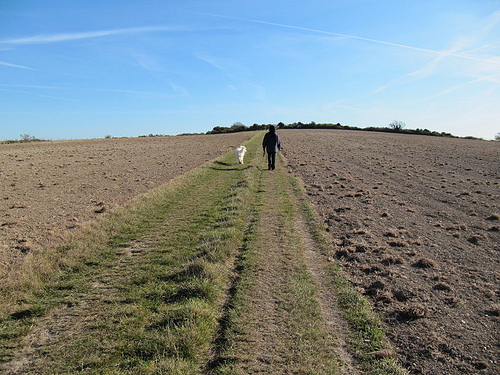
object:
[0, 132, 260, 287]
field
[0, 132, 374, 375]
road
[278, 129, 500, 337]
dirt field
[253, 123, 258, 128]
trees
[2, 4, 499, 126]
sky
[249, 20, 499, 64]
contrail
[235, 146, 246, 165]
animal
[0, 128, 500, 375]
grass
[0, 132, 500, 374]
grass strip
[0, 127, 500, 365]
dirt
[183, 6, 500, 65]
lines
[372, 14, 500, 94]
lines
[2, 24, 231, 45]
lines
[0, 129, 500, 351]
land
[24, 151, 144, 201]
soil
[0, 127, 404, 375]
field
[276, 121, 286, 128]
trees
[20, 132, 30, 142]
trees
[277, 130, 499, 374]
clumps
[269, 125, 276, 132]
head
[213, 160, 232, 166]
shadow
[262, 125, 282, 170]
man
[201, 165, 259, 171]
person's shadow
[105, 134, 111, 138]
trees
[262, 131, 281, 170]
outfit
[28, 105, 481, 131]
horizon line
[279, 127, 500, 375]
field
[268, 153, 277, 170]
black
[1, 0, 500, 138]
cloud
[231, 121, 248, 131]
tree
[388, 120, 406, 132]
tree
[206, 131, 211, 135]
shrub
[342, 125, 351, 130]
shrub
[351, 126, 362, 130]
shrub